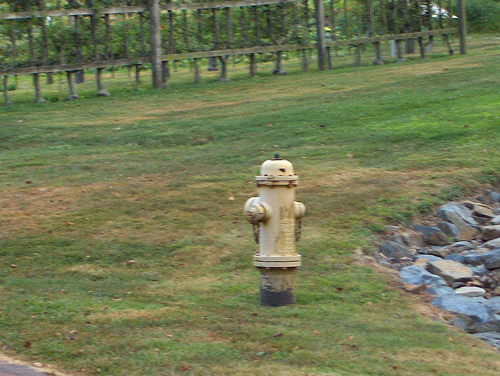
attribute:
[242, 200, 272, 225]
cap — yellow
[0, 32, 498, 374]
grass — short, green, brown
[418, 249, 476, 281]
rock — smooth, flat, jagged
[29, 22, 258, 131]
bushes — green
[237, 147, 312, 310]
fire hydrant — yellow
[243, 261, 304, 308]
base — discolored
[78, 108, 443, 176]
grass — brown, short, green